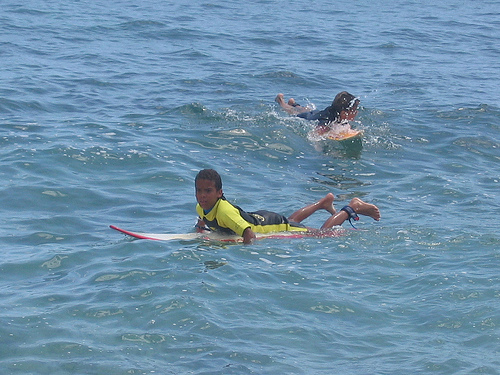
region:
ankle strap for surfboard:
[341, 204, 363, 231]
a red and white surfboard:
[97, 221, 367, 248]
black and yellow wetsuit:
[192, 204, 319, 242]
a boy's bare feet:
[321, 191, 387, 223]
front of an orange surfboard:
[326, 125, 367, 144]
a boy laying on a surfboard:
[106, 163, 388, 245]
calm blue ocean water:
[18, 27, 167, 77]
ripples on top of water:
[32, 140, 187, 173]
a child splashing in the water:
[269, 89, 379, 152]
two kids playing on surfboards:
[100, 85, 387, 251]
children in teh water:
[132, 2, 499, 332]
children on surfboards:
[157, 37, 495, 360]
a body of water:
[264, 258, 444, 353]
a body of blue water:
[314, 243, 449, 370]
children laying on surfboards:
[128, 78, 423, 372]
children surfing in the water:
[90, 41, 436, 371]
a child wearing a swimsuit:
[116, 125, 462, 355]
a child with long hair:
[154, 126, 450, 336]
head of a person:
[172, 147, 237, 203]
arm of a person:
[216, 199, 254, 253]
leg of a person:
[288, 197, 317, 233]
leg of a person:
[305, 212, 353, 241]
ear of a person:
[216, 175, 227, 204]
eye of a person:
[190, 184, 202, 198]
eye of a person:
[203, 182, 219, 193]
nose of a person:
[193, 191, 211, 201]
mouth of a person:
[193, 196, 214, 216]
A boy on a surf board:
[194, 166, 381, 239]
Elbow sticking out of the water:
[246, 234, 254, 240]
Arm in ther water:
[242, 238, 253, 242]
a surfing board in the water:
[147, 232, 193, 238]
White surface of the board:
[160, 235, 184, 238]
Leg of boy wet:
[302, 209, 309, 213]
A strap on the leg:
[347, 207, 352, 211]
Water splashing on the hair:
[351, 101, 353, 104]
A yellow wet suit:
[220, 207, 235, 220]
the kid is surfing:
[182, 171, 394, 241]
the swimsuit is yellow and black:
[198, 207, 301, 237]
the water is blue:
[163, 279, 406, 347]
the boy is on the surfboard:
[273, 79, 371, 151]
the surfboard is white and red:
[108, 222, 212, 253]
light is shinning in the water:
[142, 111, 320, 165]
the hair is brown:
[196, 167, 221, 182]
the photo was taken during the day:
[10, 11, 485, 371]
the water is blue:
[177, 82, 256, 154]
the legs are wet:
[293, 194, 337, 218]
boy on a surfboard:
[92, 143, 382, 276]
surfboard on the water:
[105, 215, 344, 252]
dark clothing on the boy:
[271, 78, 368, 139]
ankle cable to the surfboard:
[334, 200, 362, 236]